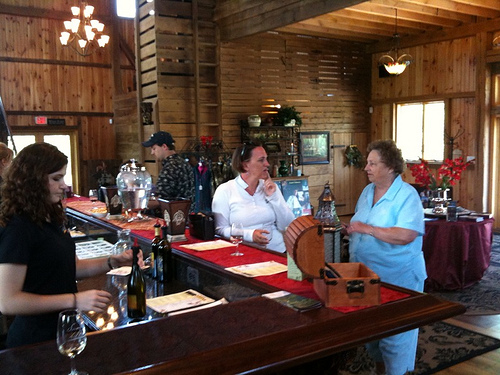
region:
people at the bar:
[110, 118, 403, 288]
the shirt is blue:
[376, 253, 423, 280]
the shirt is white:
[212, 189, 262, 216]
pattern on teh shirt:
[159, 152, 200, 194]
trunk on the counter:
[278, 223, 371, 305]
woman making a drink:
[0, 140, 110, 335]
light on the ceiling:
[65, 0, 135, 72]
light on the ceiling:
[377, 26, 418, 81]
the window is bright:
[366, 93, 466, 164]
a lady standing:
[355, 143, 425, 279]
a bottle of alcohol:
[128, 238, 144, 313]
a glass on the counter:
[53, 313, 90, 370]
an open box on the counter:
[300, 219, 376, 300]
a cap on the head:
[146, 134, 181, 148]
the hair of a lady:
[6, 154, 46, 206]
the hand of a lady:
[1, 255, 99, 315]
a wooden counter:
[113, 327, 318, 364]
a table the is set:
[425, 195, 494, 287]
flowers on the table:
[413, 157, 466, 194]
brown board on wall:
[140, 82, 160, 99]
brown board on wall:
[141, 66, 160, 87]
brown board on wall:
[135, 52, 157, 73]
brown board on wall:
[135, 30, 154, 45]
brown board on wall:
[136, 13, 155, 35]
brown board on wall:
[138, 0, 156, 20]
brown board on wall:
[286, 215, 303, 240]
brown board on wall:
[300, 217, 315, 227]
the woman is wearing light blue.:
[350, 177, 422, 371]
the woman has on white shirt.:
[213, 176, 294, 253]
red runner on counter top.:
[63, 190, 408, 313]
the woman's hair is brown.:
[3, 144, 70, 229]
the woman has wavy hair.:
[2, 142, 70, 230]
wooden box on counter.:
[287, 214, 381, 308]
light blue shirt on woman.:
[348, 179, 428, 281]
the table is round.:
[419, 197, 494, 285]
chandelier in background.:
[54, 16, 111, 53]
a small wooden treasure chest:
[285, 214, 380, 306]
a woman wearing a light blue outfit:
[346, 140, 425, 374]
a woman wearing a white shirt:
[212, 138, 294, 253]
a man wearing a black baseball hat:
[140, 128, 197, 203]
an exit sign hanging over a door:
[32, 113, 50, 127]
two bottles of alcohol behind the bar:
[151, 217, 173, 282]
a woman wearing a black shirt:
[0, 142, 112, 344]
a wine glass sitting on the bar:
[57, 310, 88, 372]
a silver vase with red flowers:
[409, 155, 473, 214]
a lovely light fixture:
[383, 56, 410, 77]